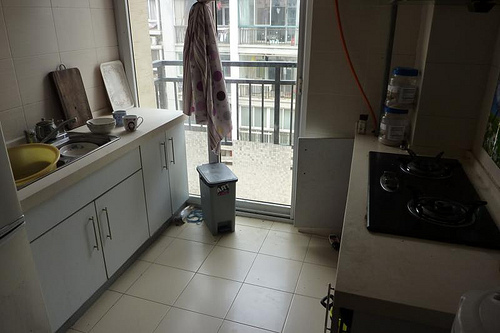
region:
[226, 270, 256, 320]
part of a floor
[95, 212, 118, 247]
part of a handle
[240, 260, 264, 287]
part of a floor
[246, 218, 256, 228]
part of a floor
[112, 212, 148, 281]
part of a board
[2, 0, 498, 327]
A kitchen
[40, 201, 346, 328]
White large tiles on the floor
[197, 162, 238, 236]
A trashcan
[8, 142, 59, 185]
A large yellow bowl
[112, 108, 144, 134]
Coffee mugs on the countertop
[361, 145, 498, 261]
A black built in the countertop stove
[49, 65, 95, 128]
A wooden cutting board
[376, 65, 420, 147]
Clear jars with blue lids stacked on top of one another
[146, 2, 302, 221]
Glass sliding doors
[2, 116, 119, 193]
A kitchen sink with dishes piled up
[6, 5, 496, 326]
a small kitchen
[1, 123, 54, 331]
a partially seen refrigerator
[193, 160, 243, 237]
a trash bin in the kitchen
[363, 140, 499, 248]
a stove top in the kitchen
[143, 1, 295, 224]
a glass sliding door leading to the patio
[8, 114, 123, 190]
a sink full of dirty dishes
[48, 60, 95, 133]
a chopping board on the counter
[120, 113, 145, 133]
a mug on the counter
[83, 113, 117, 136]
a bowl on the counter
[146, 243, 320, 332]
a tiled floor in the kitchen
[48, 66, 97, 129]
a cutting boarding leaning against a wall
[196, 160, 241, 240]
a trashcan in a kitchen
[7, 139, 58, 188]
a yellow tub in a sink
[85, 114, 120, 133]
a white bowl next to a sink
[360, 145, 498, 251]
a black stove top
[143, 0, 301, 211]
a gass kitchen door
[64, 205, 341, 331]
a tile floor in a kitchen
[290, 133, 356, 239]
an open cupboard door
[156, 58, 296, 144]
a black balcony railing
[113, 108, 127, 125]
a blue cup next to a sink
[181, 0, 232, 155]
towel hanging in front of a sliding glass door in a kitchen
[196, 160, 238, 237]
small trash can with lid and pedal for opening the lid on the floor in a kitchen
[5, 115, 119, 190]
kitchen sink filled with dirty dishes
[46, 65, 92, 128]
cutting board found near a kitchen sink on a counter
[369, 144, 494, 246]
stove top range with two coils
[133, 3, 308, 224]
glass door found in a kitchen and looking outside to a deck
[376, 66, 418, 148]
two glass jars stacked on top of each other each having blue lids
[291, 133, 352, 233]
white cabinet door wide open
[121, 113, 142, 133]
coffee cup mug found on top of a kitchen counter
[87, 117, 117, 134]
bowl resting on a kitchen counter by the sink